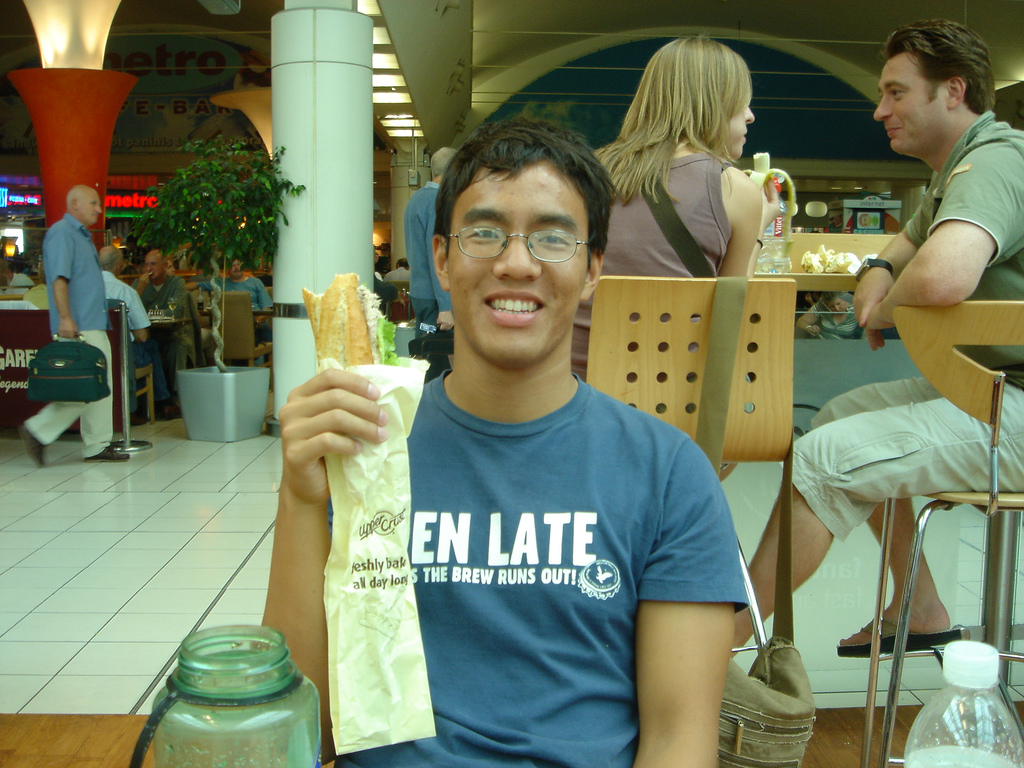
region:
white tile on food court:
[21, 671, 163, 714]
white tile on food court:
[59, 642, 180, 677]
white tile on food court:
[0, 637, 91, 676]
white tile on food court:
[90, 608, 209, 645]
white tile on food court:
[117, 585, 225, 618]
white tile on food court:
[130, 654, 182, 718]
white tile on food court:
[197, 612, 263, 639]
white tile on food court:
[67, 487, 181, 530]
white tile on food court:
[0, 487, 125, 535]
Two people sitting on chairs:
[563, 10, 1016, 668]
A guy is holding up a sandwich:
[257, 99, 754, 761]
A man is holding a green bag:
[13, 172, 143, 477]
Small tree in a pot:
[121, 125, 311, 451]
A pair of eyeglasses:
[428, 213, 605, 277]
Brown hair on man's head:
[861, 8, 1001, 168]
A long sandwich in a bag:
[295, 257, 448, 761]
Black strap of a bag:
[634, 168, 732, 289]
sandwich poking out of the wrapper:
[297, 265, 402, 384]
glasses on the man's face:
[441, 218, 590, 275]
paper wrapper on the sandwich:
[303, 350, 455, 753]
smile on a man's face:
[476, 290, 566, 325]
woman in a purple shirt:
[566, 25, 781, 377]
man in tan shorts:
[727, 0, 1022, 691]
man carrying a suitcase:
[19, 173, 140, 481]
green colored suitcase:
[29, 326, 116, 410]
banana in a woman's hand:
[738, 143, 808, 241]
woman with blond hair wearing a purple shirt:
[574, 31, 781, 402]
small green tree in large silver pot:
[128, 136, 310, 444]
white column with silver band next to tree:
[126, 1, 373, 441]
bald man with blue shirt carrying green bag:
[20, 184, 126, 469]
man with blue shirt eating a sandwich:
[258, 120, 745, 766]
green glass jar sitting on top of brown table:
[4, 623, 1022, 766]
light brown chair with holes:
[586, 276, 801, 662]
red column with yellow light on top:
[4, 0, 138, 263]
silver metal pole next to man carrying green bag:
[15, 181, 156, 467]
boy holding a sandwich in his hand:
[285, 107, 751, 763]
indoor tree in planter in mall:
[145, 123, 304, 441]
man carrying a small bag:
[17, 185, 115, 461]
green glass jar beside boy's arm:
[142, 611, 327, 766]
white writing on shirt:
[364, 497, 628, 608]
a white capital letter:
[536, 500, 581, 571]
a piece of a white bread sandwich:
[294, 277, 375, 366]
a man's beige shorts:
[782, 369, 1020, 540]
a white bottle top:
[934, 636, 1002, 685]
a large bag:
[24, 339, 108, 406]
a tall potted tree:
[122, 143, 282, 437]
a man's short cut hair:
[430, 107, 614, 267]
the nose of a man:
[868, 92, 894, 122]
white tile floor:
[0, 420, 291, 722]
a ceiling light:
[368, 72, 410, 92]